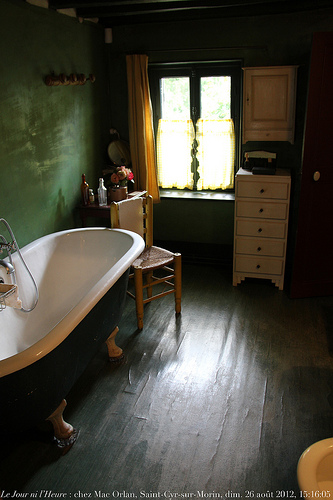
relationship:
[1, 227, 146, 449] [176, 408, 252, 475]
bathtub on floor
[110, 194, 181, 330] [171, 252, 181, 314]
chair with leg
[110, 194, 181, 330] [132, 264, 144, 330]
chair with leg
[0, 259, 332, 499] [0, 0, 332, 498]
floor of bathroom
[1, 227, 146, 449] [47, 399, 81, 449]
bathtub has claw feet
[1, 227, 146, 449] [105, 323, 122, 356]
bathtub has claw feet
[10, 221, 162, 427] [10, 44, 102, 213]
bathtub has exterior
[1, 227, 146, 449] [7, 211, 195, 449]
bathtub made of porcelain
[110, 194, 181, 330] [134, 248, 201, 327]
chair made of wood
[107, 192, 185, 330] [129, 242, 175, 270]
chair has seat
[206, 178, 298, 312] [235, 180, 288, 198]
cabinet with drawer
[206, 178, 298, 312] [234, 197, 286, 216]
cabinet with drawer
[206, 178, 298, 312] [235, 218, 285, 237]
cabinet with drawer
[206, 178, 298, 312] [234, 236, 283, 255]
cabinet with drawer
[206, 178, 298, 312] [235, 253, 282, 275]
cabinet with drawer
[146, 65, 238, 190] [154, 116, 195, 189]
window has curtain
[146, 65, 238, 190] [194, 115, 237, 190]
window has curtain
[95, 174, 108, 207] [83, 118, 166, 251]
bottle on shelf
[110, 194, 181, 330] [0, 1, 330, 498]
chair in bathroom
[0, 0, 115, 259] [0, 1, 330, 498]
wall in bathroom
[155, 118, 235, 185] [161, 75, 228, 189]
curtains leaking light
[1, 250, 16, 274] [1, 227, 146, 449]
spout of bathtub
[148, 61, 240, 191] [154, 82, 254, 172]
window with curtains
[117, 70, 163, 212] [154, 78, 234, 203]
curtain leftside of window